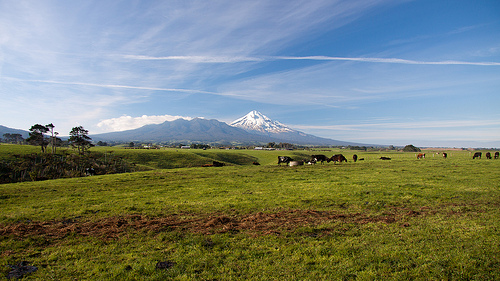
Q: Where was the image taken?
A: It was taken at the field.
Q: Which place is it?
A: It is a field.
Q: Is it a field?
A: Yes, it is a field.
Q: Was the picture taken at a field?
A: Yes, it was taken in a field.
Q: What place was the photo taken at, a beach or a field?
A: It was taken at a field.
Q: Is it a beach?
A: No, it is a field.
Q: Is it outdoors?
A: Yes, it is outdoors.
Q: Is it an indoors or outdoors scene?
A: It is outdoors.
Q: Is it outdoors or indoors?
A: It is outdoors.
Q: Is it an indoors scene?
A: No, it is outdoors.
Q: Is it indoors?
A: No, it is outdoors.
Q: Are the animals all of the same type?
A: Yes, all the animals are cows.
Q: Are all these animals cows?
A: Yes, all the animals are cows.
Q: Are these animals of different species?
A: No, all the animals are cows.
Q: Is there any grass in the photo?
A: Yes, there is grass.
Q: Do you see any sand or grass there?
A: Yes, there is grass.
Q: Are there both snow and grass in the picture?
A: Yes, there are both grass and snow.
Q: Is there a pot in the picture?
A: No, there are no pots.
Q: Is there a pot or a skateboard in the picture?
A: No, there are no pots or skateboards.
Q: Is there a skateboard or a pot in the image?
A: No, there are no pots or skateboards.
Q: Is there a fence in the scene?
A: No, there are no fences.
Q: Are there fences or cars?
A: No, there are no fences or cars.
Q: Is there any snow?
A: Yes, there is snow.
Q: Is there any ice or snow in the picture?
A: Yes, there is snow.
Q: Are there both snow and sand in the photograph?
A: No, there is snow but no sand.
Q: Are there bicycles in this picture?
A: No, there are no bicycles.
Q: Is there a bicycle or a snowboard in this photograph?
A: No, there are no bicycles or snowboards.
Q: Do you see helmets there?
A: No, there are no helmets.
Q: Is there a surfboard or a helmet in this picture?
A: No, there are no helmets or surfboards.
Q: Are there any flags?
A: No, there are no flags.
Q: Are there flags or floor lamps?
A: No, there are no flags or floor lamps.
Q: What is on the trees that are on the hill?
A: The leaves are on the trees.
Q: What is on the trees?
A: The leaves are on the trees.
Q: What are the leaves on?
A: The leaves are on the trees.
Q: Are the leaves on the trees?
A: Yes, the leaves are on the trees.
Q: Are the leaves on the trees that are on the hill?
A: Yes, the leaves are on the trees.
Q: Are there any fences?
A: No, there are no fences.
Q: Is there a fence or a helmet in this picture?
A: No, there are no fences or helmets.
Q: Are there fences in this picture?
A: No, there are no fences.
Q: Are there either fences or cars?
A: No, there are no fences or cars.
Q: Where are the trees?
A: The trees are on the hill.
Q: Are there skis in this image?
A: No, there are no skis.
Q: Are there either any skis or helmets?
A: No, there are no skis or helmets.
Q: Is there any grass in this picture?
A: Yes, there is grass.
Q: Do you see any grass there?
A: Yes, there is grass.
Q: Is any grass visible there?
A: Yes, there is grass.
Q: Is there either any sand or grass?
A: Yes, there is grass.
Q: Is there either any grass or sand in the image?
A: Yes, there is grass.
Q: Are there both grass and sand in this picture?
A: No, there is grass but no sand.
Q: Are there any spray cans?
A: No, there are no spray cans.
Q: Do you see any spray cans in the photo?
A: No, there are no spray cans.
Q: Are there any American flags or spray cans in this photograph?
A: No, there are no spray cans or American flags.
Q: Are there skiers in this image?
A: No, there are no skiers.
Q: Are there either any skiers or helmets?
A: No, there are no skiers or helmets.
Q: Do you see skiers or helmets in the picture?
A: No, there are no skiers or helmets.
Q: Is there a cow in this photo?
A: Yes, there are cows.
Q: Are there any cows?
A: Yes, there are cows.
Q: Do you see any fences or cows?
A: Yes, there are cows.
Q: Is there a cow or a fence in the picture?
A: Yes, there are cows.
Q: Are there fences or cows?
A: Yes, there are cows.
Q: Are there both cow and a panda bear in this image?
A: No, there are cows but no panda bears.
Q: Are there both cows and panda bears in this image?
A: No, there are cows but no panda bears.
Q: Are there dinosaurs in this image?
A: No, there are no dinosaurs.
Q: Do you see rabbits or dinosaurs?
A: No, there are no dinosaurs or rabbits.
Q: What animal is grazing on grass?
A: The cows are grazing on grass.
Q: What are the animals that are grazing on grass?
A: The animals are cows.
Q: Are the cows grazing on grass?
A: Yes, the cows are grazing on grass.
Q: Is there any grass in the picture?
A: Yes, there is grass.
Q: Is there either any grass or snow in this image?
A: Yes, there is grass.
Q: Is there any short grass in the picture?
A: Yes, there is short grass.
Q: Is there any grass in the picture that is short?
A: Yes, there is grass that is short.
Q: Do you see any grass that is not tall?
A: Yes, there is short grass.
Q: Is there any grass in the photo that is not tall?
A: Yes, there is short grass.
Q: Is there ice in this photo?
A: No, there is no ice.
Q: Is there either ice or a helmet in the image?
A: No, there are no ice or helmets.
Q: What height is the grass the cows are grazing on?
A: The grass is short.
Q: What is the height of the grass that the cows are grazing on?
A: The grass is short.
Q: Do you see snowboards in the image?
A: No, there are no snowboards.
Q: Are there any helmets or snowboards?
A: No, there are no snowboards or helmets.